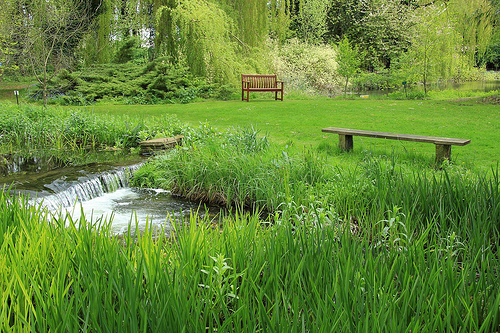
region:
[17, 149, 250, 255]
Mini waterfall property creek.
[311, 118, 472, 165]
Old long wood slab bench.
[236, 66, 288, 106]
New redwood slated bench.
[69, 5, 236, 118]
Lush foliage borders grass field.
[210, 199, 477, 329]
Weeds and tall grass forefront.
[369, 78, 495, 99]
Small pond upper right.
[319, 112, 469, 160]
Wood bench in a field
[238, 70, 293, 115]
wooden love seat in a field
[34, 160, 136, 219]
small waterfall inside of a pond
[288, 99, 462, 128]
small field of lush grass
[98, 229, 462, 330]
tall grass growing in the park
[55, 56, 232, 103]
bushes near the park bench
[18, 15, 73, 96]
small tree with no leaves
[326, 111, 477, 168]
bench surrounded by grass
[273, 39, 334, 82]
bush near the bench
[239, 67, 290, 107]
Bench in a field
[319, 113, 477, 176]
Bench in a field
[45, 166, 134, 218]
body of water in the park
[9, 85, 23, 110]
pole in the ground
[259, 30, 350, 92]
white bush in the park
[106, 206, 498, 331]
tall grass in the park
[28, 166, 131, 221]
waterfall in the pond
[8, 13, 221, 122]
large bush in the park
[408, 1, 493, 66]
tree in the park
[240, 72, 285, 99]
A wooden bench sitting on grass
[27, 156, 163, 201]
A small waterfall on the left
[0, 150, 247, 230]
A little pond on the left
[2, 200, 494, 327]
green blades of grass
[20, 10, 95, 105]
A tree in background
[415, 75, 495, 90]
A pond in background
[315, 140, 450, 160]
The shadow of a bench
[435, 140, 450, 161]
A bench leg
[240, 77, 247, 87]
A bench armrest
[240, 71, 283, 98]
A brown bench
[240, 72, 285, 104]
a bench made from wood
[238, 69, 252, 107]
an arm on the bench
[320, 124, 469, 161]
concrete blocks support a board for a bench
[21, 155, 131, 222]
a small waterfall on a creek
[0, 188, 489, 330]
tall reeds surropund the creek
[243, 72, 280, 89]
a slatted back on the far bench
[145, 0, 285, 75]
weeping willows at back of property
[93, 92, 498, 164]
bright green grass that has been mowed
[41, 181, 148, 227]
foam from the waterfall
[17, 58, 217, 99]
shorter shrubs beneath the trees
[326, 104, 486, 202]
bench that is outside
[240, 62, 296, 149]
a bench outside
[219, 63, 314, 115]
a brown bench outside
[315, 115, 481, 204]
a long beach outside